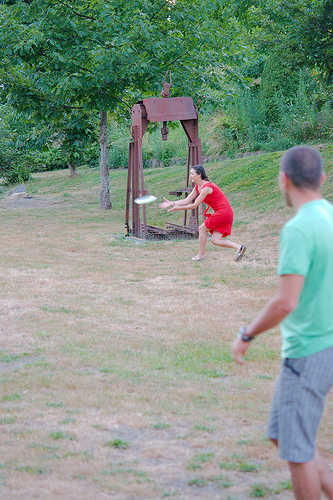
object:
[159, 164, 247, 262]
woman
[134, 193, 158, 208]
frisbee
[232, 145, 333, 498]
man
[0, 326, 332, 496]
grass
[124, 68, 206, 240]
well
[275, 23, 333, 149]
trees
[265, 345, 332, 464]
shorts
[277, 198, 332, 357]
shirt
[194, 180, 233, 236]
dress